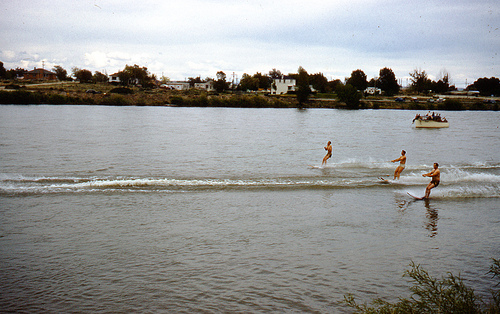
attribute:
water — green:
[1, 103, 497, 309]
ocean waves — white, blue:
[453, 166, 490, 199]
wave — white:
[0, 180, 347, 187]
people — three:
[281, 123, 496, 227]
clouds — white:
[1, 0, 498, 88]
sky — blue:
[0, 0, 499, 90]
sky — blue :
[157, 23, 257, 61]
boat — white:
[414, 117, 449, 127]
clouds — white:
[14, 32, 319, 82]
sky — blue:
[2, 5, 493, 70]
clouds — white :
[323, 16, 428, 68]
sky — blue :
[82, 0, 479, 109]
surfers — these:
[312, 137, 440, 195]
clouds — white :
[20, 8, 369, 80]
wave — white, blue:
[0, 170, 367, 202]